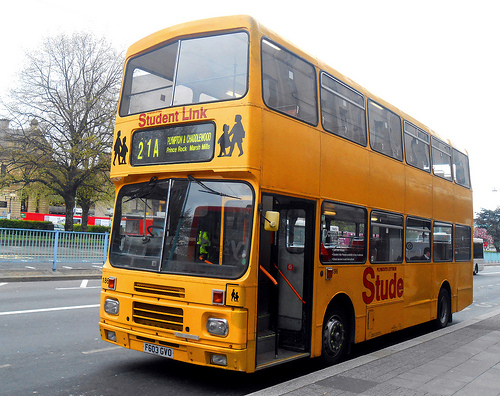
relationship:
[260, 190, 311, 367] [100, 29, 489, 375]
door on bus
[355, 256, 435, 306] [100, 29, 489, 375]
writing on bus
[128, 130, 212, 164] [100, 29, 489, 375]
sign on bus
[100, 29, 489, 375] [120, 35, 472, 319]
bus has levels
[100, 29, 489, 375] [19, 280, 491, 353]
bus on road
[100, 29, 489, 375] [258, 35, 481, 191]
bus with windows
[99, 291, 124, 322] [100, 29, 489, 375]
ligth on bus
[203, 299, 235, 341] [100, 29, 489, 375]
light on bus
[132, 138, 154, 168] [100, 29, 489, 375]
number on bus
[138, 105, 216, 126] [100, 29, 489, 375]
words on bus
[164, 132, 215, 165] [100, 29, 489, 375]
lettering on bus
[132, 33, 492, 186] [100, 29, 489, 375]
top of bus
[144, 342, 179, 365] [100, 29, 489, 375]
numbers on bus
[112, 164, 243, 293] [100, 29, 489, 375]
windshield on bus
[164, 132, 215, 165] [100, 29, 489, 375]
text on bus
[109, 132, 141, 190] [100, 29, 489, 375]
graphic on bus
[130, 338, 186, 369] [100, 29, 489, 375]
plate on bus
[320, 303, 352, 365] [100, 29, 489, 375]
wheel on bus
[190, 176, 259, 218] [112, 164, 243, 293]
blades on windshield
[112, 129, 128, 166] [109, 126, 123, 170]
graphic of children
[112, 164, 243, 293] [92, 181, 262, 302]
window with wipers